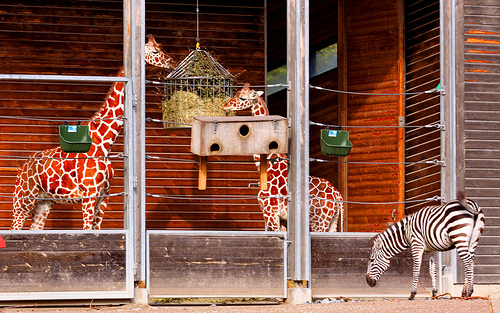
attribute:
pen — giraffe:
[61, 19, 417, 270]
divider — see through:
[102, 201, 331, 292]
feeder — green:
[312, 118, 347, 165]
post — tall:
[277, 20, 326, 290]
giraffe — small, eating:
[203, 74, 362, 258]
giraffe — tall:
[22, 16, 153, 268]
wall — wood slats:
[327, 20, 415, 229]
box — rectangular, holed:
[198, 100, 330, 168]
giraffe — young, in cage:
[217, 58, 344, 248]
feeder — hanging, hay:
[152, 31, 242, 140]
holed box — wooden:
[195, 108, 288, 168]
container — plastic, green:
[42, 98, 101, 168]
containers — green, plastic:
[52, 74, 375, 189]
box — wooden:
[183, 101, 291, 167]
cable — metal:
[295, 73, 451, 129]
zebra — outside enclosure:
[329, 164, 498, 301]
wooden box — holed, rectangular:
[186, 105, 354, 175]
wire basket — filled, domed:
[142, 28, 244, 140]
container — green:
[51, 107, 92, 167]